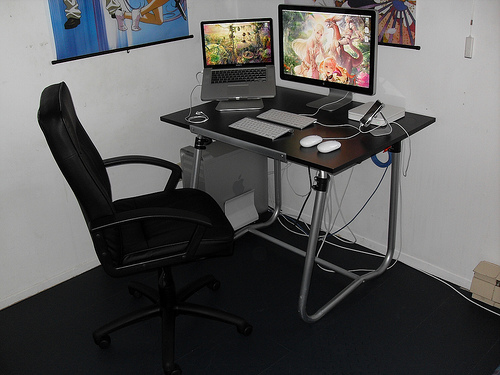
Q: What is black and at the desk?
A: The chair.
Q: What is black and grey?
A: The desk.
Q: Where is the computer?
A: On the floor.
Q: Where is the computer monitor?
A: On the desk.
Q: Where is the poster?
A: On the wall.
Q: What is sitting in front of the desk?
A: A chair.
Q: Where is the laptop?
A: On the desk.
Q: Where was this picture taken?
A: In an office.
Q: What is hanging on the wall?
A: Posters.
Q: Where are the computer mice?
A: On the desk.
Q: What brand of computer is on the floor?
A: Apple.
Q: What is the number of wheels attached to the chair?
A: Five.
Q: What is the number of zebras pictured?
A: Zero.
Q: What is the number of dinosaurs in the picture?
A: Zero.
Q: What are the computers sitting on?
A: A desk.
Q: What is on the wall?
A: Poster.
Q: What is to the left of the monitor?
A: Laptop.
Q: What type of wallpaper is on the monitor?
A: Animation.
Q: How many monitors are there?
A: Two.